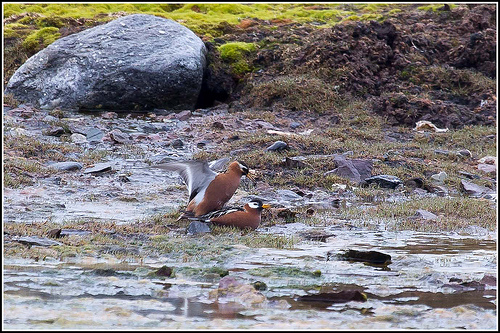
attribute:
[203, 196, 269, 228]
bird — crouched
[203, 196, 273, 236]
bird — mating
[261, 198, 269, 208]
beak — bright orange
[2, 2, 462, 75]
moss — short, green, growing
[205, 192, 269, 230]
bird — black, white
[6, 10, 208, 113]
boulder — big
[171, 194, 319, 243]
bird — laying down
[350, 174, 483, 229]
grass — green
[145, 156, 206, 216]
wing — gray, flapping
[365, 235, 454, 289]
water — running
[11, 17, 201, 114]
rock — big, grey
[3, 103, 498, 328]
water — not clear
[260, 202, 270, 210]
beak — orange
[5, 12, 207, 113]
rock — gray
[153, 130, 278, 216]
bird — stretching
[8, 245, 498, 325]
pond — muddy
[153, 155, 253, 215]
bird — sitting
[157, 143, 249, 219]
bird — black, white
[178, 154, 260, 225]
bird — black, white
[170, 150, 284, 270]
bodies — red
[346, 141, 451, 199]
rocks — sharp